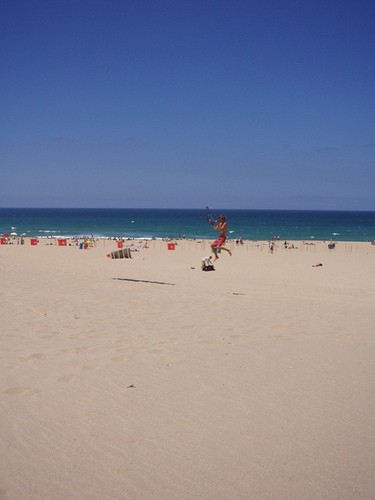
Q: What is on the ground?
A: Sand.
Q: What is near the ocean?
A: People on the sand.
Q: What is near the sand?
A: The ocean.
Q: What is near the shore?
A: People relaxing at the beach.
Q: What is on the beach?
A: Beach chairs, towels and people.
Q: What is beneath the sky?
A: The ocean.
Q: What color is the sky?
A: Blue.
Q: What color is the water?
A: Blue and white.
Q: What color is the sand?
A: Brown.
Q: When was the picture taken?
A: Daytime.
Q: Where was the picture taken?
A: At the beach.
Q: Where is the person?
A: In the air.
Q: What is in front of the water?
A: The sand.